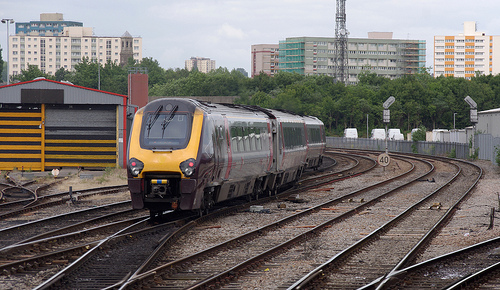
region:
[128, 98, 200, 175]
Yellow paint on train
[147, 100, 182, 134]
2 windshield wipers on window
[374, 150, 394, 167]
Number 40 on circle sign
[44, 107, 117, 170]
striped garage door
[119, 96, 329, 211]
Passenger train on tracks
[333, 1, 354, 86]
tall radio tower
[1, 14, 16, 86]
Street light on gray pole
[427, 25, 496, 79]
orange and white building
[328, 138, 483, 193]
curved train tracks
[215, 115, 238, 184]
Passenger train door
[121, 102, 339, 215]
Yellow and silver train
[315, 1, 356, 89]
Satellite tower in the background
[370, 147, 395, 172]
Forty sign on the train tracks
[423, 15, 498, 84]
Yellow and white building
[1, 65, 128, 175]
Gray, yellow, and black building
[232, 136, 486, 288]
Empty train tracks next to train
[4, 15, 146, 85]
White building in the background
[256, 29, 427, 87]
Gray and green building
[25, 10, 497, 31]
Gray sky above the train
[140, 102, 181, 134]
Train windshield wipers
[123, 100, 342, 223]
a train with three cars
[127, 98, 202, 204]
the front of the train is yellow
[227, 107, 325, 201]
the train cars are silver with red stripes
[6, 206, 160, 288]
the train tracks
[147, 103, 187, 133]
windshield wipers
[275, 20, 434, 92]
a tall building in the background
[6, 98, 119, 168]
the gates on this building are yellow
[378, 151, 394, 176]
the sign has the number 40 on it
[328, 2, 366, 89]
a big metal tower stands in the background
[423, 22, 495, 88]
this building appears to be a high rise apartment building.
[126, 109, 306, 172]
this is a train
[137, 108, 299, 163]
the train is long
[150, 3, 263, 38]
this is the sky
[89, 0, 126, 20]
the sky is blue in color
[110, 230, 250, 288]
these are railway line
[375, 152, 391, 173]
this is a signpost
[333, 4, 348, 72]
this is a satelite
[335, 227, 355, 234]
these are small rocks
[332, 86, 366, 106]
these are many trees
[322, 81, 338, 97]
the tree has green leaves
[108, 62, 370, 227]
a train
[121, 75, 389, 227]
a train on the tracks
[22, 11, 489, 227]
a train entering a city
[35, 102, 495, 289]
a mulititude of train tracks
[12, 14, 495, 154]
buildings in the background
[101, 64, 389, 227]
a silver and yellow train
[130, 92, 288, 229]
the caboose has a yellow end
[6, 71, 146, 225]
a garage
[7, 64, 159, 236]
the garage has yellow stripes on the doors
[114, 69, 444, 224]
the train croses over two sets of tracks